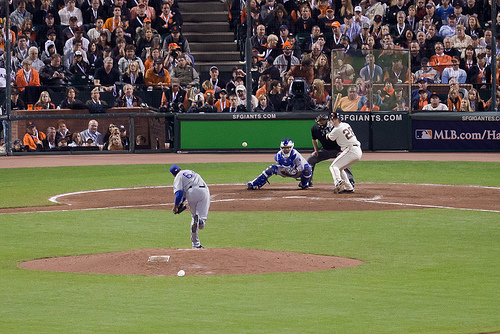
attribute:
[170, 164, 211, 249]
pitcher — thowing, throwing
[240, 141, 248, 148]
ball — midair, white, flying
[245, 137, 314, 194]
catcher — waiting, ready, protected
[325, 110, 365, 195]
batter — ready, standing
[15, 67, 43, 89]
jacket — orange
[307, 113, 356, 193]
umpire — watching, ready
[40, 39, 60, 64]
fan — watching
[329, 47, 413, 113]
fence — protection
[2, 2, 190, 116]
bleacher — full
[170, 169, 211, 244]
uniform — blue, numbered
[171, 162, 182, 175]
cap — blue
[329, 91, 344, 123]
bat — brown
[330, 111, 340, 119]
lid — black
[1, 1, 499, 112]
stadium — full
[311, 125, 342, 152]
shirt — black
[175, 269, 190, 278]
bag — white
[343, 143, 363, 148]
belt — black